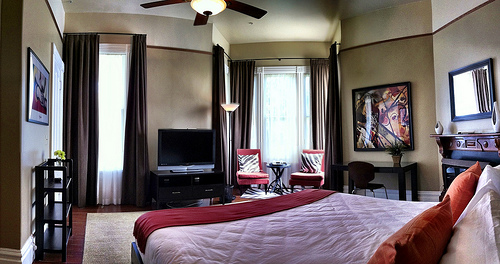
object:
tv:
[157, 129, 216, 173]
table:
[149, 168, 226, 209]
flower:
[54, 150, 61, 157]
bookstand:
[34, 159, 73, 264]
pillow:
[367, 193, 454, 264]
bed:
[129, 161, 499, 264]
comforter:
[132, 189, 441, 264]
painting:
[353, 85, 410, 148]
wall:
[0, 0, 65, 264]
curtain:
[63, 34, 101, 206]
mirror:
[450, 64, 489, 117]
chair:
[236, 149, 269, 197]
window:
[232, 65, 338, 189]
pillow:
[237, 153, 261, 173]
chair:
[348, 161, 389, 200]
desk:
[330, 161, 419, 202]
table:
[266, 162, 292, 195]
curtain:
[471, 67, 491, 113]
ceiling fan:
[138, 1, 268, 26]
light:
[190, 0, 228, 17]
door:
[49, 42, 63, 225]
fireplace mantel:
[429, 133, 500, 203]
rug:
[82, 212, 143, 264]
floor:
[66, 205, 138, 264]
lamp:
[219, 103, 241, 203]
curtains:
[230, 61, 256, 188]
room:
[0, 0, 499, 263]